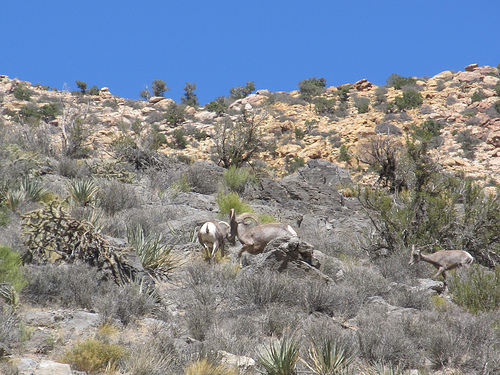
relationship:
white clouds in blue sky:
[170, 32, 221, 67] [0, 1, 499, 109]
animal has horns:
[226, 207, 299, 269] [222, 202, 246, 232]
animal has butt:
[197, 219, 233, 266] [199, 222, 216, 242]